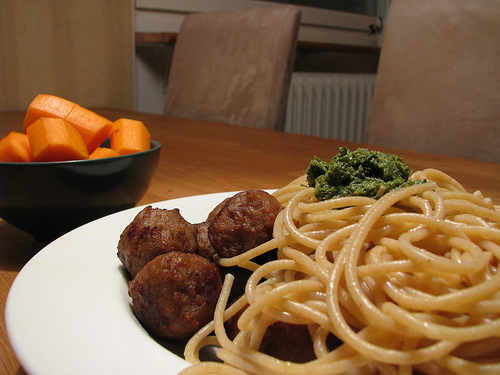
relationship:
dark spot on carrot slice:
[108, 125, 120, 135] [105, 112, 153, 153]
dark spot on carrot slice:
[108, 125, 120, 135] [20, 89, 114, 156]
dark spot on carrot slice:
[108, 125, 120, 135] [21, 115, 90, 161]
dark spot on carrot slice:
[108, 125, 120, 135] [83, 142, 120, 160]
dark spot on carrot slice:
[108, 125, 120, 135] [0, 125, 32, 162]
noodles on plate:
[178, 167, 499, 374] [31, 284, 129, 349]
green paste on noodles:
[304, 145, 427, 201] [304, 146, 408, 197]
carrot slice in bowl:
[27, 115, 91, 162] [0, 172, 117, 212]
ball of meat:
[203, 187, 280, 263] [222, 205, 261, 233]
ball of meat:
[112, 205, 198, 280] [137, 222, 174, 247]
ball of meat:
[130, 253, 227, 342] [147, 265, 203, 305]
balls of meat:
[118, 184, 289, 346] [143, 259, 198, 310]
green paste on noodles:
[304, 145, 427, 201] [182, 139, 496, 368]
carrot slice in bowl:
[23, 93, 114, 156] [0, 132, 161, 243]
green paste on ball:
[311, 148, 418, 201] [117, 204, 198, 278]